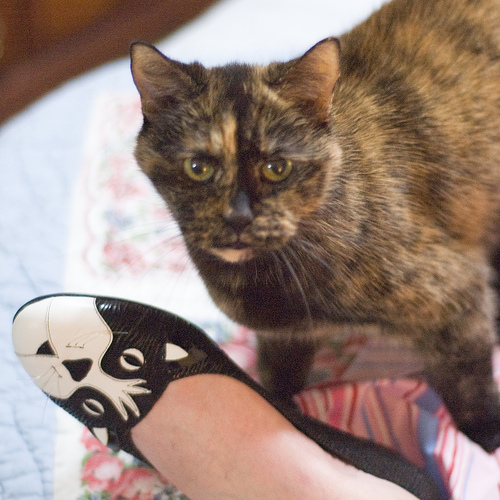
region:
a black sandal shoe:
[10, 268, 410, 492]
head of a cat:
[111, 15, 366, 270]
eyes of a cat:
[166, 135, 305, 193]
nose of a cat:
[227, 191, 257, 221]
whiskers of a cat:
[145, 191, 374, 322]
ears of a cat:
[112, 43, 370, 115]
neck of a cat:
[192, 253, 377, 344]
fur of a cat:
[365, 96, 475, 179]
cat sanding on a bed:
[109, 6, 494, 411]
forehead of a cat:
[185, 69, 315, 148]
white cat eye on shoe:
[117, 344, 143, 371]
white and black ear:
[160, 334, 204, 368]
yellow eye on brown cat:
[257, 151, 299, 188]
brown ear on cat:
[278, 34, 350, 117]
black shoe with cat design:
[7, 295, 177, 426]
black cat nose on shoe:
[57, 354, 99, 383]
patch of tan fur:
[218, 116, 238, 150]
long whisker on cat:
[280, 250, 325, 344]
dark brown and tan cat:
[127, 36, 342, 259]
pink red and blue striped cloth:
[327, 384, 392, 429]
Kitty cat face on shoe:
[3, 281, 193, 458]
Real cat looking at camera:
[136, 103, 499, 438]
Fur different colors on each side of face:
[173, 118, 300, 194]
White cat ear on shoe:
[155, 318, 202, 373]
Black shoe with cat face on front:
[10, 281, 449, 498]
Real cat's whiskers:
[265, 196, 387, 343]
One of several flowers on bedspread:
[69, 432, 129, 497]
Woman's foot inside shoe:
[157, 346, 403, 498]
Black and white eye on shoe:
[117, 336, 147, 376]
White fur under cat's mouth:
[210, 233, 250, 268]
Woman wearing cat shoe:
[15, 301, 203, 448]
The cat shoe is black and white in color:
[7, 297, 439, 461]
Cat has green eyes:
[162, 149, 308, 182]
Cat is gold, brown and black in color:
[125, 44, 497, 317]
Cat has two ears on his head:
[125, 28, 351, 117]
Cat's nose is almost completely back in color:
[223, 183, 255, 227]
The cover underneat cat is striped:
[298, 391, 499, 487]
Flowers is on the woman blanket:
[76, 445, 152, 498]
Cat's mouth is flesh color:
[207, 244, 263, 262]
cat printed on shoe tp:
[15, 283, 186, 434]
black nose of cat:
[63, 355, 93, 377]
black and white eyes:
[72, 340, 157, 423]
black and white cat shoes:
[16, 300, 416, 498]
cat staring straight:
[111, 13, 498, 350]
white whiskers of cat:
[278, 227, 351, 308]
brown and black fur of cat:
[337, 83, 457, 242]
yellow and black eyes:
[259, 154, 295, 188]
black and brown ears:
[278, 40, 342, 110]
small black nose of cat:
[218, 193, 260, 229]